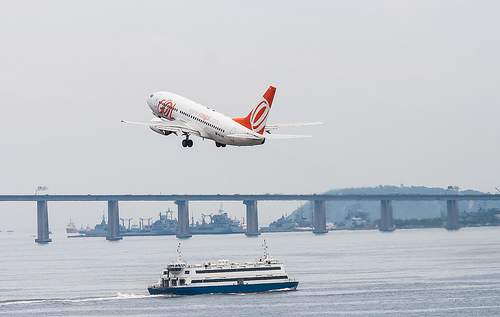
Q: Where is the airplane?
A: In the sky.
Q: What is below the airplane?
A: A ship.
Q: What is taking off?
A: Plane.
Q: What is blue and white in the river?
A: Ship.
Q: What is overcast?
A: Sky.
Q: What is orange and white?
A: Plane.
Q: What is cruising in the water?
A: Boat.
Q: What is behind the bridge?
A: Ships.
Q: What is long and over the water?
A: Bridge.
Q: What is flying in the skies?
A: A plane.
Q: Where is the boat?
A: In the water under the plane.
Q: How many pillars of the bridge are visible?
A: Seven.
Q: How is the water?
A: Calm.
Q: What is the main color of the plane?
A: White.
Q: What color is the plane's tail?
A: Red and white.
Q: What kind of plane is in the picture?
A: Commercial.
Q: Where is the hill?
A: Behind the bridge.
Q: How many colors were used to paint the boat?
A: Two.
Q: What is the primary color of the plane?
A: White.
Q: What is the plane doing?
A: Taking off.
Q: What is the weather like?
A: Cloudy.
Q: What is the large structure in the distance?
A: A bridge.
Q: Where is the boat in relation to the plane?
A: Underneath the plane.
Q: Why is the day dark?
A: Cloudy.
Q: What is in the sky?
A: A plane.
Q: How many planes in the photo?
A: One.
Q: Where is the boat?
A: The water.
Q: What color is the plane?
A: White and red.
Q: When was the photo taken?
A: Day time.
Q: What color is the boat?
A: Blue and white.